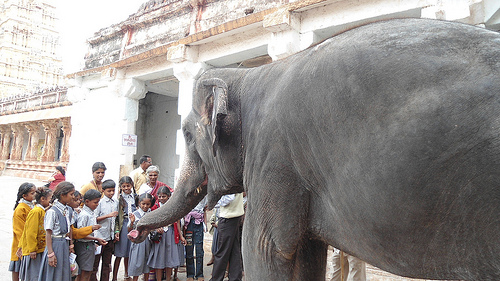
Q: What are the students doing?
A: Feeding an elephant.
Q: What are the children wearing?
A: School uniforms.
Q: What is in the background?
A: An old building with pillars.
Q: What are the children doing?
A: Playing with the elephant.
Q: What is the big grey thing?
A: An elephant.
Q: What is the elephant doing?
A: Playing with children.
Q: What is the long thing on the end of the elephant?
A: Its trunk.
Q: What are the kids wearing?
A: School uniforms.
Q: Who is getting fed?
A: The elephant.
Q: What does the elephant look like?
A: It's big and gray.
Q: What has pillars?
A: The building in the background.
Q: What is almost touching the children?
A: Trunk.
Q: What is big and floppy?
A: Ears.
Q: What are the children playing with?
A: Elephant.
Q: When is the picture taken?
A: Daytime.